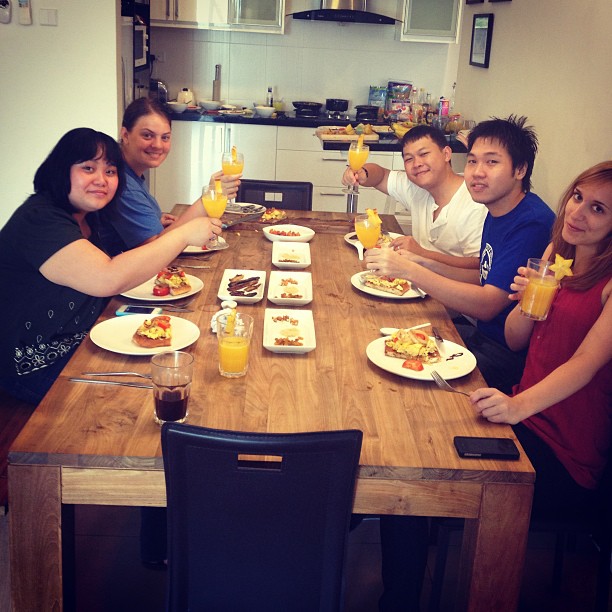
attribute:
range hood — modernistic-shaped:
[292, 2, 397, 37]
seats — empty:
[206, 166, 399, 604]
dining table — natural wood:
[10, 199, 538, 610]